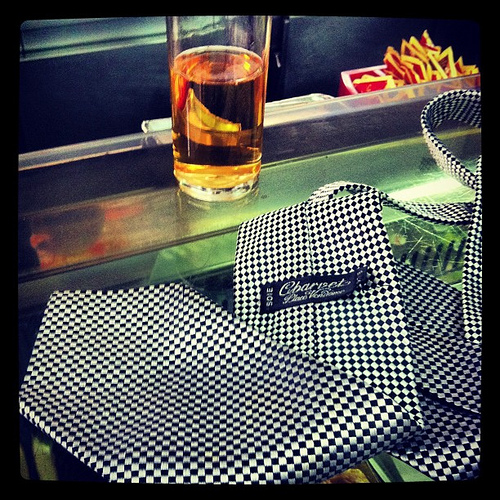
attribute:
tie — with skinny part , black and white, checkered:
[23, 88, 481, 482]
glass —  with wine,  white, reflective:
[161, 22, 264, 210]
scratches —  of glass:
[396, 211, 467, 279]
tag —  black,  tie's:
[260, 267, 377, 317]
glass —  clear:
[160, 12, 267, 198]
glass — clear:
[162, 5, 272, 204]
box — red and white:
[318, 35, 472, 105]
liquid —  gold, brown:
[174, 47, 268, 190]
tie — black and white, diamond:
[68, 243, 362, 417]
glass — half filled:
[154, 15, 279, 220]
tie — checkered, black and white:
[62, 213, 440, 475]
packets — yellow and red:
[371, 33, 468, 85]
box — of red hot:
[335, 22, 494, 99]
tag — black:
[257, 263, 372, 315]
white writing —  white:
[261, 278, 351, 306]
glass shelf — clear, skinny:
[20, 117, 480, 298]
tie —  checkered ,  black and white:
[99, 286, 392, 468]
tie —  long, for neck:
[21, 153, 471, 498]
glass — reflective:
[21, 138, 228, 318]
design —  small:
[158, 364, 181, 385]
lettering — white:
[276, 277, 349, 307]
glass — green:
[17, 127, 481, 482]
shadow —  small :
[176, 85, 256, 165]